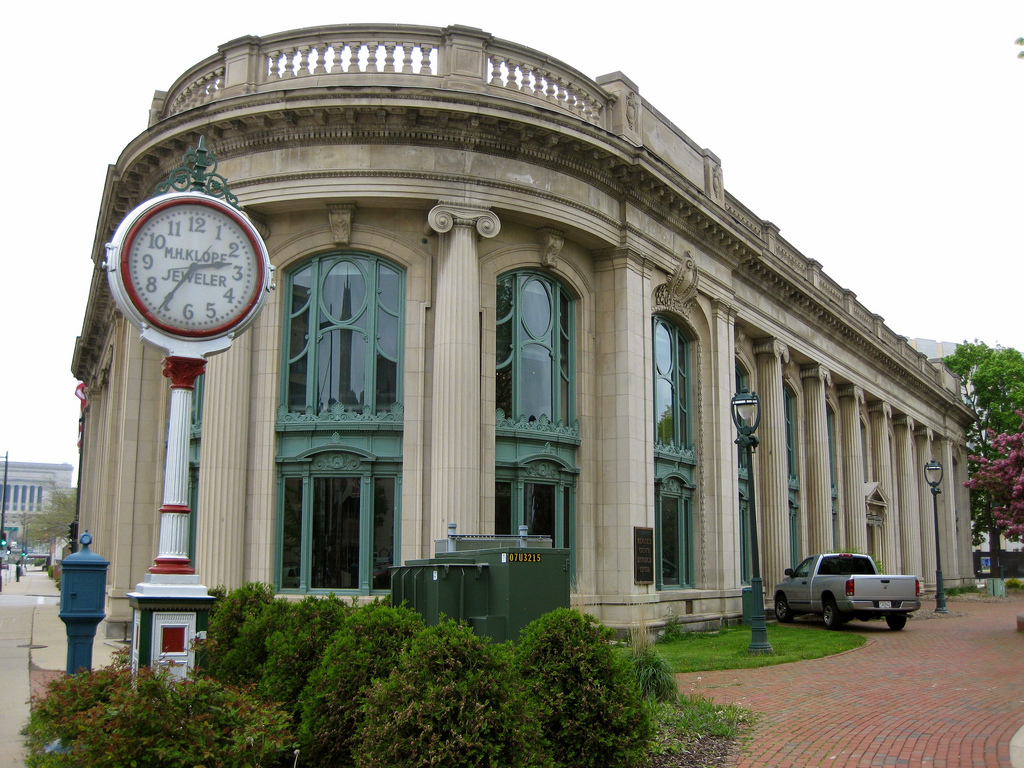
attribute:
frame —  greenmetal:
[307, 282, 372, 397]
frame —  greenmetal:
[512, 302, 577, 398]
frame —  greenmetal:
[506, 479, 565, 523]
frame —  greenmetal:
[663, 365, 683, 417]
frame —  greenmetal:
[670, 494, 697, 553]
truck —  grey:
[767, 513, 962, 626]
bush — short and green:
[505, 600, 622, 724]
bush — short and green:
[415, 663, 470, 739]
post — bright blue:
[41, 499, 145, 768]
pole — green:
[750, 520, 777, 585]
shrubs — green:
[300, 628, 493, 687]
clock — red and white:
[87, 185, 293, 389]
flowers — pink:
[990, 445, 1019, 497]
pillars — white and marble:
[13, 479, 53, 514]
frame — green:
[525, 364, 578, 410]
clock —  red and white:
[136, 213, 253, 352]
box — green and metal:
[357, 496, 606, 721]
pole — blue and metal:
[50, 520, 113, 735]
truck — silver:
[771, 552, 923, 624]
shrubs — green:
[15, 577, 688, 765]